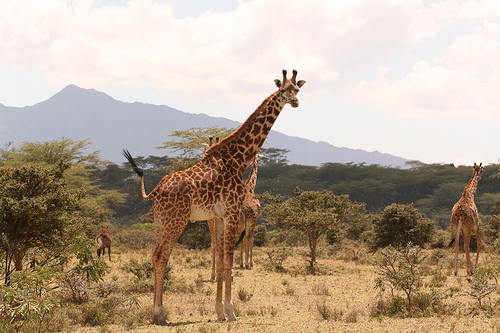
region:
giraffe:
[143, 60, 304, 319]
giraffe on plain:
[100, 65, 306, 315]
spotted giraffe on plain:
[90, 61, 296, 316]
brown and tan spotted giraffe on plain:
[95, 65, 300, 310]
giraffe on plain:
[445, 150, 485, 250]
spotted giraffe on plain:
[445, 155, 486, 262]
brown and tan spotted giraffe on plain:
[438, 152, 488, 257]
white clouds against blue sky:
[6, 14, 478, 64]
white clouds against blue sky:
[327, 21, 472, 137]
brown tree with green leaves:
[19, 157, 100, 297]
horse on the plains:
[92, 223, 122, 263]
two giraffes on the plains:
[120, 67, 480, 327]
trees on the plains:
[276, 190, 438, 324]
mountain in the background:
[11, 70, 92, 285]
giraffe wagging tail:
[111, 67, 307, 331]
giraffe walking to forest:
[447, 162, 483, 278]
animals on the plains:
[93, 67, 487, 322]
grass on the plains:
[263, 272, 358, 327]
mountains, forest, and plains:
[299, 125, 377, 319]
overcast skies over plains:
[20, 5, 238, 82]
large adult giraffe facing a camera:
[132, 85, 312, 293]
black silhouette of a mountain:
[12, 83, 379, 165]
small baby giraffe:
[77, 214, 119, 267]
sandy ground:
[272, 269, 371, 320]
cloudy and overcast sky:
[30, 15, 491, 135]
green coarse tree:
[6, 162, 95, 269]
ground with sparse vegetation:
[301, 287, 349, 332]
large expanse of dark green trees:
[295, 157, 453, 204]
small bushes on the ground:
[125, 258, 154, 293]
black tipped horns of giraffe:
[275, 68, 299, 82]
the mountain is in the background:
[27, 93, 179, 130]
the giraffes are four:
[153, 96, 486, 318]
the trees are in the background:
[326, 163, 430, 195]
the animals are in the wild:
[5, 92, 487, 328]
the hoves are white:
[150, 306, 251, 326]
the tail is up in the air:
[122, 158, 158, 205]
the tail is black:
[118, 154, 149, 179]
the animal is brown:
[96, 218, 126, 266]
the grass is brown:
[270, 278, 346, 332]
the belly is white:
[191, 206, 209, 228]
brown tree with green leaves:
[289, 196, 342, 263]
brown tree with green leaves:
[374, 191, 430, 242]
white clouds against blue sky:
[4, 4, 231, 76]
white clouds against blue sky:
[213, 6, 415, 63]